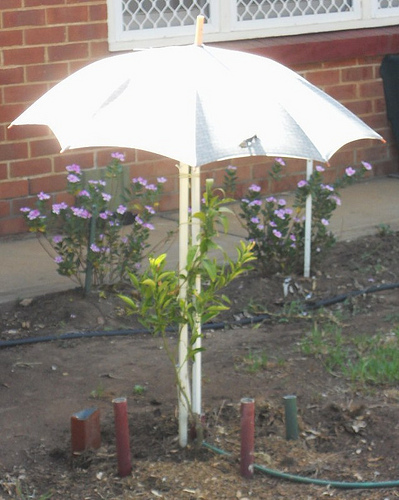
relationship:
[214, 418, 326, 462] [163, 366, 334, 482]
hose in garden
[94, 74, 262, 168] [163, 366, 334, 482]
umbrella in garden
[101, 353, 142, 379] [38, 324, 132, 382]
dirt on ground